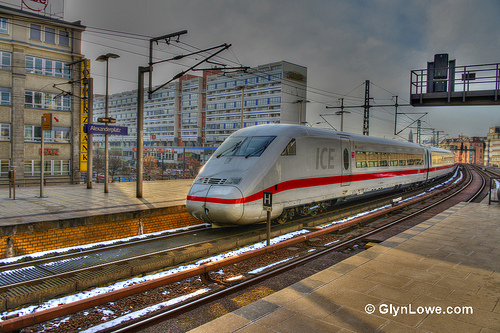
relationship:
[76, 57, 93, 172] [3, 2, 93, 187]
sign on building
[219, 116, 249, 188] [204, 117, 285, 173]
wipers for winshield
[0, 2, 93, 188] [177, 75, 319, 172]
building a building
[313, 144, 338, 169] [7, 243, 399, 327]
"ice" train on tracks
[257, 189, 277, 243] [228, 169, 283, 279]
sign on track with letter h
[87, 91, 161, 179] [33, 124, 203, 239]
sign on station platorm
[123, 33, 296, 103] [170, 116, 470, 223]
power lines above highspeed train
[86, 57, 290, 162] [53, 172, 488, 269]
buildings near tracks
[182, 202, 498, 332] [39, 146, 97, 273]
platform for travelers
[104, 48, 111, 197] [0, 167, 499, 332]
light pole near tracks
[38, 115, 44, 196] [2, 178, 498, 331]
pole in ground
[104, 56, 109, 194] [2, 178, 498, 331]
pole in ground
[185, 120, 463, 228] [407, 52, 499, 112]
train on platform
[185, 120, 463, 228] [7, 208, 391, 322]
train on tracks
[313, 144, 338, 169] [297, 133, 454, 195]
"ice" on side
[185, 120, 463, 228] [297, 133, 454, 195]
train has side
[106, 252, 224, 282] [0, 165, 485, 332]
snow on tracks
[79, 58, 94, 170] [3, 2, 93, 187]
lettering on building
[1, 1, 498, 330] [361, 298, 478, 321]
photo has web address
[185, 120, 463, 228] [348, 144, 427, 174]
train has windows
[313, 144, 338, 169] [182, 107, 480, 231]
"ice" on train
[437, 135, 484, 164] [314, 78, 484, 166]
building standing in distance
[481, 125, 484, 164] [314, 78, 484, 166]
building standing in distance